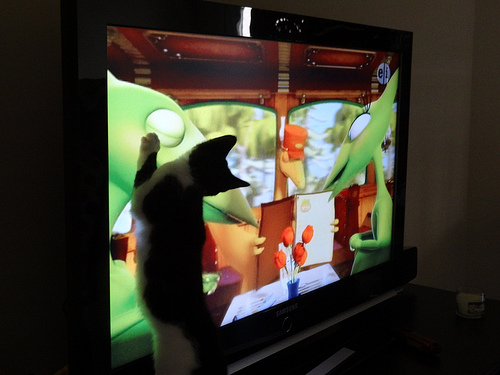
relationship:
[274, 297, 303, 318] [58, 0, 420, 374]
company name on front of tv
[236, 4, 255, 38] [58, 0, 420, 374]
light reflection on tv frame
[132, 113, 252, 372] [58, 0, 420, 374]
cat leaning on tv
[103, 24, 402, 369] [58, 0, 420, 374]
image on tv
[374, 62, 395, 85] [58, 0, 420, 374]
channel logo on screen of tv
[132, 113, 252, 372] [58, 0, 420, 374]
cat standing on tv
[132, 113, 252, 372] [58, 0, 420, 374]
cat watching tv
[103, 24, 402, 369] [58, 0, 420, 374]
cartoon on tv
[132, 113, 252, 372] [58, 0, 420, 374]
cat touching tv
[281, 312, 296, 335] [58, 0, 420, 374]
power button on tv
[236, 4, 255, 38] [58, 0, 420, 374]
light reflecting off of tv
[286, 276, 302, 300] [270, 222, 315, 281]
vase with tulips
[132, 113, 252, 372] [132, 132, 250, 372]
cat trying to get cat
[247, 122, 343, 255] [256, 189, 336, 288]
bird looking at menu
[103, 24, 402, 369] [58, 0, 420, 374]
tv show on tv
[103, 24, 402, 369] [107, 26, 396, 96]
train has a roof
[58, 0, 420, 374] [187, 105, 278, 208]
train has a window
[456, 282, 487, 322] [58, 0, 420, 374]
jar sitting by tv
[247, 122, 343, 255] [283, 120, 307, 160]
bird wearing a hat